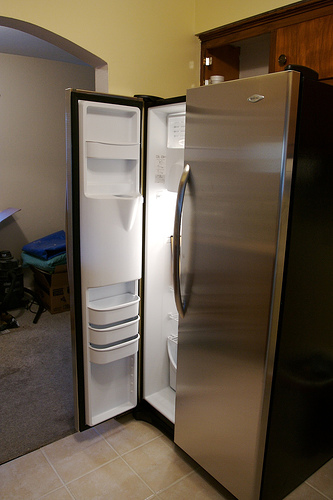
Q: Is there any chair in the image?
A: No, there are no chairs.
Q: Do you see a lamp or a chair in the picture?
A: No, there are no chairs or lamps.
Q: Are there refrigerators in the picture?
A: Yes, there is a refrigerator.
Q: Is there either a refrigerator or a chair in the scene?
A: Yes, there is a refrigerator.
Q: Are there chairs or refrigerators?
A: Yes, there is a refrigerator.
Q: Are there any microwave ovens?
A: No, there are no microwave ovens.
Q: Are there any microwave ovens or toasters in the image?
A: No, there are no microwave ovens or toasters.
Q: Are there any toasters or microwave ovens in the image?
A: No, there are no microwave ovens or toasters.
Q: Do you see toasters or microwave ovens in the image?
A: No, there are no microwave ovens or toasters.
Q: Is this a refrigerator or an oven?
A: This is a refrigerator.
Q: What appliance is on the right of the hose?
A: The appliance is a refrigerator.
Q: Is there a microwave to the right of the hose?
A: No, there is a refrigerator to the right of the hose.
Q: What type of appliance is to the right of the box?
A: The appliance is a refrigerator.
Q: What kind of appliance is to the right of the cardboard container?
A: The appliance is a refrigerator.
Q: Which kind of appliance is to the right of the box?
A: The appliance is a refrigerator.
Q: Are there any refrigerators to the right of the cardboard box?
A: Yes, there is a refrigerator to the right of the box.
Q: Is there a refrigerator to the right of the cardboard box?
A: Yes, there is a refrigerator to the right of the box.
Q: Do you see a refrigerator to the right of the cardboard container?
A: Yes, there is a refrigerator to the right of the box.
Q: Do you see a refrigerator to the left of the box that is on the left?
A: No, the refrigerator is to the right of the box.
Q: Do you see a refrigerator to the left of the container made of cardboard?
A: No, the refrigerator is to the right of the box.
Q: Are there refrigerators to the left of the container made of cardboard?
A: No, the refrigerator is to the right of the box.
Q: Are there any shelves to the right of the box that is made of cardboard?
A: No, there is a refrigerator to the right of the box.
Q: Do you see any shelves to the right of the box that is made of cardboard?
A: No, there is a refrigerator to the right of the box.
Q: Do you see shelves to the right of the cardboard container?
A: No, there is a refrigerator to the right of the box.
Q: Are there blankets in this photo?
A: Yes, there is a blanket.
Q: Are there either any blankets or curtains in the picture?
A: Yes, there is a blanket.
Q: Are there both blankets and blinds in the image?
A: No, there is a blanket but no blinds.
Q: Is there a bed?
A: No, there are no beds.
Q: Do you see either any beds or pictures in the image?
A: No, there are no beds or pictures.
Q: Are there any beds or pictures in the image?
A: No, there are no beds or pictures.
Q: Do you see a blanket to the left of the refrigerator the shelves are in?
A: Yes, there is a blanket to the left of the refrigerator.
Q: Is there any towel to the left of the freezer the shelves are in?
A: No, there is a blanket to the left of the freezer.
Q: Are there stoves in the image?
A: No, there are no stoves.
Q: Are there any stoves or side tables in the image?
A: No, there are no stoves or side tables.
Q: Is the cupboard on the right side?
A: Yes, the cupboard is on the right of the image.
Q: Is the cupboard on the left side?
A: No, the cupboard is on the right of the image.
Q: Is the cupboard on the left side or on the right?
A: The cupboard is on the right of the image.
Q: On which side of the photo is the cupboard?
A: The cupboard is on the right of the image.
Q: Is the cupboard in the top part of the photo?
A: Yes, the cupboard is in the top of the image.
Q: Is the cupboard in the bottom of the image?
A: No, the cupboard is in the top of the image.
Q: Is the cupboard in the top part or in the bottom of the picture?
A: The cupboard is in the top of the image.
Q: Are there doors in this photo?
A: Yes, there is a door.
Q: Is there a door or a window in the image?
A: Yes, there is a door.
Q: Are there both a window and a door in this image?
A: No, there is a door but no windows.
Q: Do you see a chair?
A: No, there are no chairs.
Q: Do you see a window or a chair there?
A: No, there are no chairs or windows.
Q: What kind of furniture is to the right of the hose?
A: The pieces of furniture are shelves.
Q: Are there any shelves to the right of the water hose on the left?
A: Yes, there are shelves to the right of the water hose.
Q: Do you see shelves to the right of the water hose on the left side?
A: Yes, there are shelves to the right of the water hose.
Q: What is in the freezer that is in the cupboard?
A: The shelves are in the freezer.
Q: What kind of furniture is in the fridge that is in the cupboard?
A: The pieces of furniture are shelves.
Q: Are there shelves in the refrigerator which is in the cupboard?
A: Yes, there are shelves in the refrigerator.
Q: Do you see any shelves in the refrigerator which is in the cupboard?
A: Yes, there are shelves in the refrigerator.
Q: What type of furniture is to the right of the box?
A: The pieces of furniture are shelves.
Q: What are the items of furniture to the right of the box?
A: The pieces of furniture are shelves.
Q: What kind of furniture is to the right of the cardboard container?
A: The pieces of furniture are shelves.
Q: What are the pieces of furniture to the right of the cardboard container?
A: The pieces of furniture are shelves.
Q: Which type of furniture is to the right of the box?
A: The pieces of furniture are shelves.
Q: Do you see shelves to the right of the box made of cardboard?
A: Yes, there are shelves to the right of the box.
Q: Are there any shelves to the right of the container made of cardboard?
A: Yes, there are shelves to the right of the box.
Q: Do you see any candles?
A: No, there are no candles.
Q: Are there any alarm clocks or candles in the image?
A: No, there are no candles or alarm clocks.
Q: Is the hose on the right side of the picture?
A: No, the hose is on the left of the image.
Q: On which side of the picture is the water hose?
A: The water hose is on the left of the image.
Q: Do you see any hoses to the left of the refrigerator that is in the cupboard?
A: Yes, there is a hose to the left of the fridge.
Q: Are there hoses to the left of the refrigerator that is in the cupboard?
A: Yes, there is a hose to the left of the fridge.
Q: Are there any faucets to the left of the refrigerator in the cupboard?
A: No, there is a hose to the left of the refrigerator.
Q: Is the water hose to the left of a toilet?
A: No, the water hose is to the left of the freezer.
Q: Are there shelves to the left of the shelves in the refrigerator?
A: No, there is a hose to the left of the shelves.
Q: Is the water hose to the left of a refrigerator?
A: Yes, the water hose is to the left of a refrigerator.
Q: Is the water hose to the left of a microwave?
A: No, the water hose is to the left of a refrigerator.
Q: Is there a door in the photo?
A: Yes, there is a door.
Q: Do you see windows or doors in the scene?
A: Yes, there is a door.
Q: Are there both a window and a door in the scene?
A: No, there is a door but no windows.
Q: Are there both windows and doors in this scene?
A: No, there is a door but no windows.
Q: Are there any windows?
A: No, there are no windows.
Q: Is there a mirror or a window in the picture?
A: No, there are no windows or mirrors.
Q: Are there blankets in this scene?
A: Yes, there is a blanket.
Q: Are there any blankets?
A: Yes, there is a blanket.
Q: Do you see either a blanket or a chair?
A: Yes, there is a blanket.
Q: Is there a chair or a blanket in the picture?
A: Yes, there is a blanket.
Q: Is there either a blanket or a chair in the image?
A: Yes, there is a blanket.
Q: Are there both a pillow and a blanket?
A: No, there is a blanket but no pillows.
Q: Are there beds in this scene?
A: No, there are no beds.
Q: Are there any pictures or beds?
A: No, there are no beds or pictures.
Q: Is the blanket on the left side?
A: Yes, the blanket is on the left of the image.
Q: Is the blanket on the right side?
A: No, the blanket is on the left of the image.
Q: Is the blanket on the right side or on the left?
A: The blanket is on the left of the image.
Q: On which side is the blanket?
A: The blanket is on the left of the image.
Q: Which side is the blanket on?
A: The blanket is on the left of the image.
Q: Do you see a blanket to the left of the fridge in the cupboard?
A: Yes, there is a blanket to the left of the refrigerator.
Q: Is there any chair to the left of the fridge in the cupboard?
A: No, there is a blanket to the left of the refrigerator.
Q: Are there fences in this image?
A: No, there are no fences.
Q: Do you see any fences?
A: No, there are no fences.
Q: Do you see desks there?
A: No, there are no desks.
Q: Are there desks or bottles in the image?
A: No, there are no desks or bottles.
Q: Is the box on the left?
A: Yes, the box is on the left of the image.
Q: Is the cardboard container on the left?
A: Yes, the box is on the left of the image.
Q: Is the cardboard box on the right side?
A: No, the box is on the left of the image.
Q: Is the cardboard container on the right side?
A: No, the box is on the left of the image.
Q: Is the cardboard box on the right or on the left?
A: The box is on the left of the image.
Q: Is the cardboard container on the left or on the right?
A: The box is on the left of the image.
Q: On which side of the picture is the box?
A: The box is on the left of the image.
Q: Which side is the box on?
A: The box is on the left of the image.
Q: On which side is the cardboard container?
A: The box is on the left of the image.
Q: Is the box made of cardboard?
A: Yes, the box is made of cardboard.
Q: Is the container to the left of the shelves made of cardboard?
A: Yes, the box is made of cardboard.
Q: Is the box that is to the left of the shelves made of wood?
A: No, the box is made of cardboard.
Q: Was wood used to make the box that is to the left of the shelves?
A: No, the box is made of cardboard.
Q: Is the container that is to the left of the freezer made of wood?
A: No, the box is made of cardboard.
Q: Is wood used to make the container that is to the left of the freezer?
A: No, the box is made of cardboard.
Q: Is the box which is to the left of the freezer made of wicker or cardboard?
A: The box is made of cardboard.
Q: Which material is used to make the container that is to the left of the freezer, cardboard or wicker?
A: The box is made of cardboard.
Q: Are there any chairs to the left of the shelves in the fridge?
A: No, there is a box to the left of the shelves.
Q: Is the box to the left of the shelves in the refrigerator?
A: Yes, the box is to the left of the shelves.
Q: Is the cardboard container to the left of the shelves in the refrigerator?
A: Yes, the box is to the left of the shelves.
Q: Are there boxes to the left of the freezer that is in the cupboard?
A: Yes, there is a box to the left of the refrigerator.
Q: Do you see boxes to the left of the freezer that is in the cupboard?
A: Yes, there is a box to the left of the refrigerator.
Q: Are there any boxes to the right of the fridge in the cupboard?
A: No, the box is to the left of the freezer.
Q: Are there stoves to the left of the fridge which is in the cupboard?
A: No, there is a box to the left of the freezer.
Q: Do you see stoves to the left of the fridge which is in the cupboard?
A: No, there is a box to the left of the freezer.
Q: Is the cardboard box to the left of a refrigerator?
A: Yes, the box is to the left of a refrigerator.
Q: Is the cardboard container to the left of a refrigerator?
A: Yes, the box is to the left of a refrigerator.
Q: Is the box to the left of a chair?
A: No, the box is to the left of a refrigerator.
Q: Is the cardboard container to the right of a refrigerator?
A: No, the box is to the left of a refrigerator.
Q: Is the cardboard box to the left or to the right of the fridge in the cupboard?
A: The box is to the left of the freezer.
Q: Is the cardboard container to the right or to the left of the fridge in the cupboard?
A: The box is to the left of the freezer.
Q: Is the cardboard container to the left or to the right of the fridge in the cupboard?
A: The box is to the left of the freezer.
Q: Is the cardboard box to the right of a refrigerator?
A: No, the box is to the left of a refrigerator.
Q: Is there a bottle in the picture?
A: No, there are no bottles.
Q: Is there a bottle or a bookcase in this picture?
A: No, there are no bottles or bookcases.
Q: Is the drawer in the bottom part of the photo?
A: Yes, the drawer is in the bottom of the image.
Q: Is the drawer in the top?
A: No, the drawer is in the bottom of the image.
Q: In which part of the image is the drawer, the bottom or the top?
A: The drawer is in the bottom of the image.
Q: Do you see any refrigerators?
A: Yes, there is a refrigerator.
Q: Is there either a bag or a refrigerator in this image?
A: Yes, there is a refrigerator.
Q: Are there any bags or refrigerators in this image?
A: Yes, there is a refrigerator.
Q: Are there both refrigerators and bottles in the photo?
A: No, there is a refrigerator but no bottles.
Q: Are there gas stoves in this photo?
A: No, there are no gas stoves.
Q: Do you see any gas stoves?
A: No, there are no gas stoves.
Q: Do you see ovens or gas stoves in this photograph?
A: No, there are no gas stoves or ovens.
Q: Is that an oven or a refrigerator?
A: That is a refrigerator.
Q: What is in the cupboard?
A: The fridge is in the cupboard.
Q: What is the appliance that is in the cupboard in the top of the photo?
A: The appliance is a refrigerator.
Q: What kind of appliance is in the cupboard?
A: The appliance is a refrigerator.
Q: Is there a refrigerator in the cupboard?
A: Yes, there is a refrigerator in the cupboard.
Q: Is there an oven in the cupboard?
A: No, there is a refrigerator in the cupboard.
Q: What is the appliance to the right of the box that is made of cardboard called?
A: The appliance is a refrigerator.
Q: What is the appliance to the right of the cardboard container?
A: The appliance is a refrigerator.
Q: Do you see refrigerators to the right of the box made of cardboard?
A: Yes, there is a refrigerator to the right of the box.